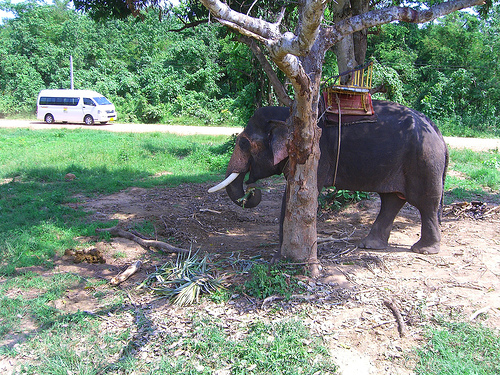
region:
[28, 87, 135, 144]
a big white car riding along the road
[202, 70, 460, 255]
a big black walking elephant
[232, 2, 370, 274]
a tree in front of an elephant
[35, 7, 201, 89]
a bunch of trees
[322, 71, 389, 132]
an elephants saddle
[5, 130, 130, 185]
green grass in the sunlight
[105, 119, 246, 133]
the sandy road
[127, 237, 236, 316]
tree branches on the ground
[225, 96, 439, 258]
an elephant walking n the ground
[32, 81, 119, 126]
a white car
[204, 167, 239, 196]
the tusk of an elephant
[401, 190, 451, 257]
the leg of an elephant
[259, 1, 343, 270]
the trunk of a tree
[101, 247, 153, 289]
a rock on the ground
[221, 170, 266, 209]
the trunk of an elephant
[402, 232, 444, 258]
the foot of an elephant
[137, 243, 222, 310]
leaves on the ground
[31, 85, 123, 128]
a white van on the road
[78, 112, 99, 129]
a black wheel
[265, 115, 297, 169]
the ear of an elephant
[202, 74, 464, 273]
elephant behind a tree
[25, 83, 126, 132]
small white passenger bus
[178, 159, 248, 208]
white elephant tusk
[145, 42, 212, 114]
lush green bushes and trees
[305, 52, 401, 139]
saddle on top of elephant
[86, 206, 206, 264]
root of tree sticking up through ground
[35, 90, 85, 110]
black windows on passenger bus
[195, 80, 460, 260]
small brown and grey elephant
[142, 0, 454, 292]
large tree in front of elephant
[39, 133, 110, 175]
field of green grass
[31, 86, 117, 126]
Bus transporting tourists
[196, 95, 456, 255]
Elephant eating sticks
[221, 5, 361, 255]
Elephant amongst trees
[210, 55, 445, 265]
Elephant that can take people around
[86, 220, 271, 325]
Sticks and leaves dropped from trees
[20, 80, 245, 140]
Tourist bus traveling on single lane road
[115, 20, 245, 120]
Thick trees and shrubs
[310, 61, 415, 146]
Seat on an elephant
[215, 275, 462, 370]
Torn up grass and sand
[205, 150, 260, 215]
Elephant tusk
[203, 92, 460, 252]
Elephant in the trees.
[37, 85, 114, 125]
White van in the background.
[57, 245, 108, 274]
Elephant feces on the ground.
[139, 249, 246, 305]
Top of palm trees on the ground.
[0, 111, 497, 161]
Dirt road in the background.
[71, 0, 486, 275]
Tree in the foreground.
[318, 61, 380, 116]
Chair on top of elephant.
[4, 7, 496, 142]
Green trees in the background.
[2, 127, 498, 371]
Grass on the ground.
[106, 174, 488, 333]
Dirt on the ground.